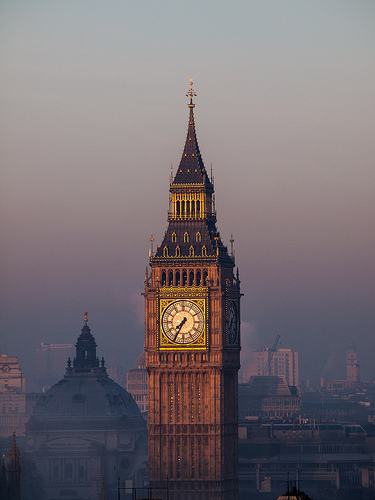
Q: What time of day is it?
A: Dusk.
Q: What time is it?
A: 7:35.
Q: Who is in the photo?
A: Nobody.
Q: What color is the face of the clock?
A: White.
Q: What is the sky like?
A: Hazy.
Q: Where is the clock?
A: On the tower.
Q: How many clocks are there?
A: One.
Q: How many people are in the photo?
A: None.